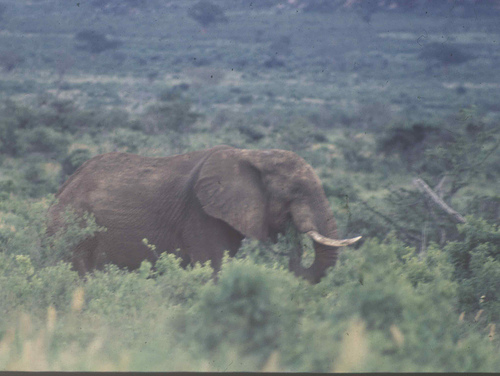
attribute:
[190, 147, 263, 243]
ear — large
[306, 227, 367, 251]
tusk — ivory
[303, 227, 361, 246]
tusk — large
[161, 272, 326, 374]
bush — green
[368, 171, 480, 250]
logs — dead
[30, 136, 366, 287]
elephant — gray, very big, eating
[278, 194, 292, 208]
eye — small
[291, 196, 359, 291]
trunk — elephant's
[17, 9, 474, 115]
brush — green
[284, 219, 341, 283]
trunk — curled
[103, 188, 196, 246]
skin — wrinkly